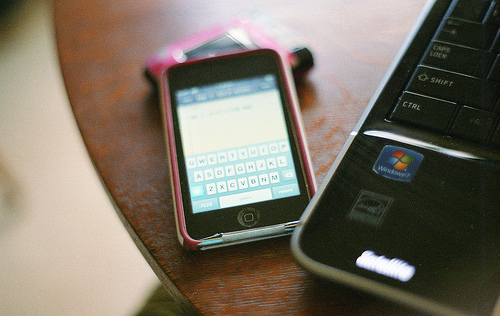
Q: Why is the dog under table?
A: No dog.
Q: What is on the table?
A: Cell phones.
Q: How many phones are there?
A: Two.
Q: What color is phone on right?
A: Black.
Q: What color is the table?
A: Brown.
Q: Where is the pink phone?
A: On left.